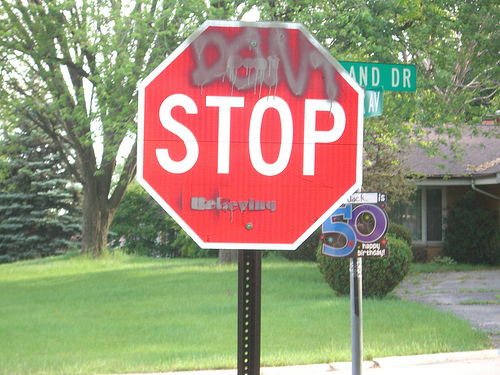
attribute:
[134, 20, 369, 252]
sign — red, bolted, white, standing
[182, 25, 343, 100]
graffiti — painted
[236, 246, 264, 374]
pole — holed, black, metal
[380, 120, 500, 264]
house — one story, background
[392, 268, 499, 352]
driveway — concrete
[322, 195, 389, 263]
sign — number , hanging, purple, written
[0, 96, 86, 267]
tree — spruce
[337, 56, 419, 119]
sign — green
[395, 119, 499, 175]
roof — light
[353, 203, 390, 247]
zero — purple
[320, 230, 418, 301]
tree — green, sitting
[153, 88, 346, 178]
letters — white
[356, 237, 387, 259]
words — white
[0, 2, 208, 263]
tree — large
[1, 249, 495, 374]
grass — green